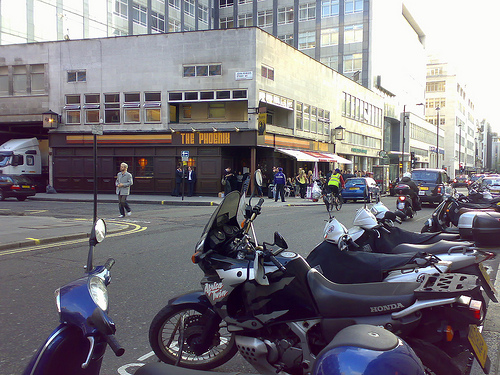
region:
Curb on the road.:
[38, 185, 195, 272]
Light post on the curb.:
[24, 97, 186, 289]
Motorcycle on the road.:
[162, 163, 443, 370]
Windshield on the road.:
[148, 172, 396, 301]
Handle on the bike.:
[159, 205, 235, 284]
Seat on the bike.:
[278, 239, 480, 368]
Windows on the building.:
[67, 69, 174, 128]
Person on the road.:
[99, 132, 154, 246]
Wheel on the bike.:
[141, 272, 259, 364]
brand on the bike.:
[362, 279, 417, 319]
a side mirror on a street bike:
[86, 216, 117, 248]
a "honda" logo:
[369, 302, 405, 312]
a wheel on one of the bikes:
[153, 300, 243, 370]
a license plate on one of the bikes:
[471, 316, 495, 368]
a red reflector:
[468, 293, 486, 324]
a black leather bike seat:
[312, 264, 420, 321]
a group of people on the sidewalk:
[271, 160, 325, 198]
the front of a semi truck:
[1, 137, 38, 177]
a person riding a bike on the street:
[393, 172, 419, 219]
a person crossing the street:
[113, 158, 141, 222]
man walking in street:
[114, 160, 136, 226]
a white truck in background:
[0, 134, 44, 203]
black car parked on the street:
[2, 172, 38, 201]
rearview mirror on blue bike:
[78, 218, 123, 251]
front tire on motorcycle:
[148, 290, 233, 371]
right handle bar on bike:
[252, 193, 275, 214]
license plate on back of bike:
[465, 322, 496, 363]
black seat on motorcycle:
[310, 268, 434, 319]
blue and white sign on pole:
[181, 147, 191, 163]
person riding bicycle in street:
[319, 168, 350, 209]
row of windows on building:
[180, 64, 224, 78]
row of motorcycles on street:
[325, 207, 480, 282]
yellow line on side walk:
[19, 234, 42, 244]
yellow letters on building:
[179, 131, 229, 145]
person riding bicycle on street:
[324, 169, 346, 212]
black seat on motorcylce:
[305, 266, 415, 321]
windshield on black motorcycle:
[198, 187, 241, 247]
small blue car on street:
[345, 175, 378, 197]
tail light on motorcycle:
[437, 322, 456, 347]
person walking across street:
[111, 160, 134, 216]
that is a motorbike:
[164, 276, 484, 359]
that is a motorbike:
[312, 240, 486, 275]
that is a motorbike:
[349, 225, 454, 248]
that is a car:
[341, 174, 376, 201]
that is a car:
[411, 165, 447, 191]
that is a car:
[463, 210, 497, 235]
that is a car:
[451, 169, 470, 197]